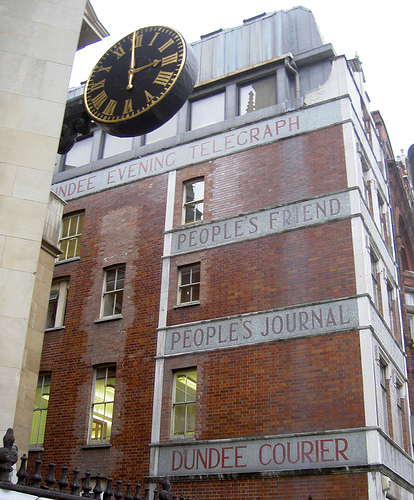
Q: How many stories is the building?
A: Four.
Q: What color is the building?
A: Red.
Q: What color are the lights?
A: Yellow.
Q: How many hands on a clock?
A: 2.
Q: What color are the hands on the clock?
A: Gold.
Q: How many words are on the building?
A: 9.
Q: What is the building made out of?
A: Brick.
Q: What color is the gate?
A: Black.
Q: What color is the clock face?
A: Black.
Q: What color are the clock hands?
A: Gold.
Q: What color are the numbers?
A: Gold.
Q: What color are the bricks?
A: Red.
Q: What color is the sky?
A: White.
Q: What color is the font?
A: Red.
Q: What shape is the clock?
A: Round.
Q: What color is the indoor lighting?
A: Yellow.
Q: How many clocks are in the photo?
A: One.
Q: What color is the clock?
A: Black and gold.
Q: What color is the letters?
A: Red.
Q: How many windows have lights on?
A: Three.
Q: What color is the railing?
A: Black.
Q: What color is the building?
A: Red and gray.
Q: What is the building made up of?
A: Brick.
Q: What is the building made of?
A: Brick.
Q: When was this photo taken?
A: Three o'clock.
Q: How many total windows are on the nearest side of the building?
A: Thirteen.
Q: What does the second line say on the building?
A: People's Friend.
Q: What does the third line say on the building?
A: People's Journal.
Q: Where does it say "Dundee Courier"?
A: Fourth Line.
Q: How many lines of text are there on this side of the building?
A: Four.